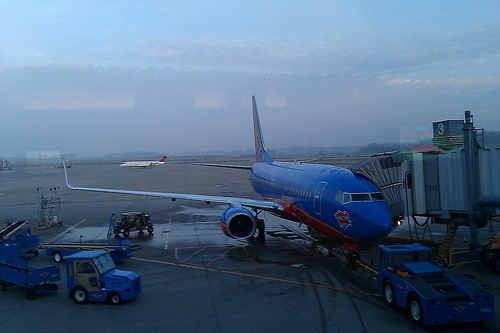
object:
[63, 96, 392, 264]
plane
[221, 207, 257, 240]
engine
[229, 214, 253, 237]
turbine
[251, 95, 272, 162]
fin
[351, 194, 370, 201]
window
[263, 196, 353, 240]
stripe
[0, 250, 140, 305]
vehicle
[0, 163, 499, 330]
tarmac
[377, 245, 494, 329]
cart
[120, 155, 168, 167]
plane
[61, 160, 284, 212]
wing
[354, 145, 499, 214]
walkway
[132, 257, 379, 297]
line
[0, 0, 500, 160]
sky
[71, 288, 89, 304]
tire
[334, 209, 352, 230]
symbol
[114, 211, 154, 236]
vehicle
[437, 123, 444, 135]
number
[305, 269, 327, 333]
line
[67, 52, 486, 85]
cloud